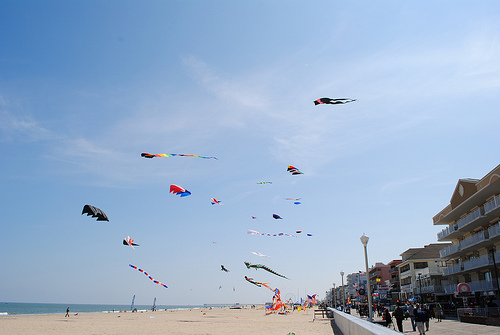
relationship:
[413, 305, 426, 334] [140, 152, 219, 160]
people flying kite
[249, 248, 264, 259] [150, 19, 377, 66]
white kite flying in air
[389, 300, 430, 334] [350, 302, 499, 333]
people walking on sidewalk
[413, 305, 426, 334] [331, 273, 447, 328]
people on boardwalk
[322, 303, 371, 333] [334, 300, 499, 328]
rail splitting boardwalk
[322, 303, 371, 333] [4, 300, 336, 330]
rail splitting beach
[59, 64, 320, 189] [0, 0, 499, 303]
clouds in sky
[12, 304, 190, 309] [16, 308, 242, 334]
ocean next to sand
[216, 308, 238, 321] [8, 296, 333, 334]
sand on beach